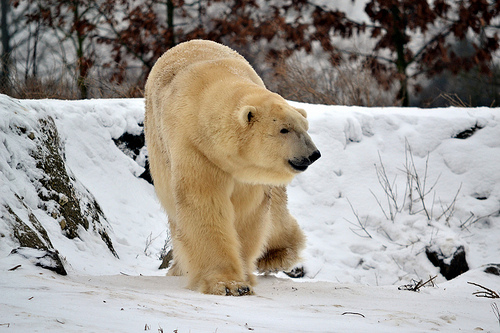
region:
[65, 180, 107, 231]
edge of a rock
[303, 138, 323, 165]
face of a bear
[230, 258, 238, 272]
foot of a bear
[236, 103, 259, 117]
ear of a bear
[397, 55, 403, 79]
edge of a branch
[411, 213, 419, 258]
part of the snow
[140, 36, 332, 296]
Big white bear walking in the snow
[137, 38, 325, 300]
Fuzzy white bear walking in the snow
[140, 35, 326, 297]
Polar bear on the prowl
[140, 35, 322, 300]
Dirty white polar bear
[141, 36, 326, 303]
Polar bear walking on all fours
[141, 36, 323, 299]
Animal well-suited for the snow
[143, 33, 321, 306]
Bear found only in colder regions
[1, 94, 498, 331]
Snow covered hillside in the winter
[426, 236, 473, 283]
Black rock lying on the ground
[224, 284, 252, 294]
Claws on a polar bear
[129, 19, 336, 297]
large polar bear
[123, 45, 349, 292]
large white bear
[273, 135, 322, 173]
brown and black snout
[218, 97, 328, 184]
large head of polar bear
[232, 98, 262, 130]
perky whit ear of bear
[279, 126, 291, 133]
small black eye of bear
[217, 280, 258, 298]
black feet and claws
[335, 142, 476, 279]
sticks of plant covered in snow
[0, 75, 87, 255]
mountain side covered in snow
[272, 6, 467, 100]
trees covered in snow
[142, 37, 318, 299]
the animal on the snow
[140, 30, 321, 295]
the polar bear on the snow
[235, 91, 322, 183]
the head of the polar bear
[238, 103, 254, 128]
the ear on the polar bear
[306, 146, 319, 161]
the nose on the polar bear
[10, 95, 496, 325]
the snow on the ground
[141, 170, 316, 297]
the legs on the polar bear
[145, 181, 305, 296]
the legs on the animal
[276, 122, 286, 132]
the eye on the animal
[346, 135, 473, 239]
the short branches sticking out of the snow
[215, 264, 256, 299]
edge of a leg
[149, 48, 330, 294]
the bear is big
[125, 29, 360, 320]
Large white polar bear in the snow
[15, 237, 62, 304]
Snow covering the ground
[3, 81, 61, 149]
Snow covering the ground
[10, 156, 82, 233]
Snow covering the ground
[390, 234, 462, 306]
Snow covering the ground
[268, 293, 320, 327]
Snow covering the ground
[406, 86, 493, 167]
Snow covering the ground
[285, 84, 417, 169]
Snow covering the ground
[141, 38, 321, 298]
large white polar bear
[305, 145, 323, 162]
black polar bear nose